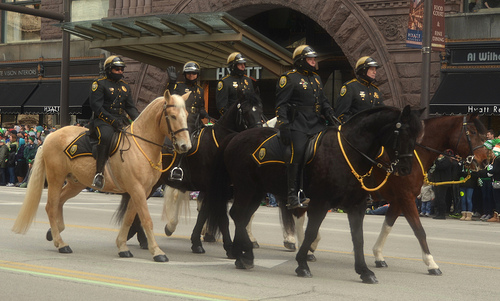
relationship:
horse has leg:
[52, 135, 150, 237] [128, 186, 145, 208]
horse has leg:
[52, 135, 150, 237] [46, 161, 59, 181]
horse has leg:
[52, 135, 150, 237] [65, 184, 75, 194]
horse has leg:
[198, 99, 436, 285] [318, 191, 325, 224]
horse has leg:
[198, 99, 436, 285] [349, 211, 364, 238]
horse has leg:
[198, 99, 436, 285] [239, 172, 247, 192]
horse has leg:
[198, 99, 436, 285] [256, 195, 261, 204]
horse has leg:
[433, 120, 474, 140] [399, 191, 412, 208]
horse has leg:
[433, 120, 474, 140] [387, 212, 398, 223]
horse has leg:
[433, 120, 474, 140] [294, 215, 301, 226]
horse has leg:
[198, 133, 213, 154] [201, 189, 216, 203]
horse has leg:
[198, 133, 213, 154] [215, 209, 224, 224]